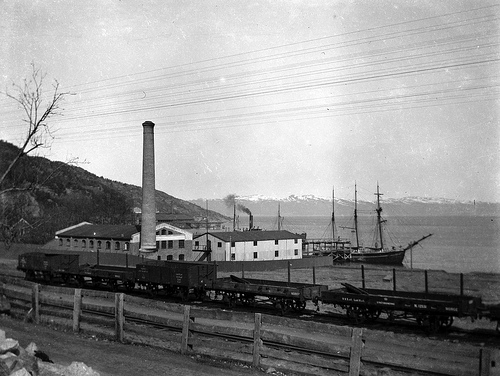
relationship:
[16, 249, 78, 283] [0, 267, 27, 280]
car on rail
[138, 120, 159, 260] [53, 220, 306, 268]
smokestack on factory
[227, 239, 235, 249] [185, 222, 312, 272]
windows on factory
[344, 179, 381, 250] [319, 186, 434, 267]
mast on boat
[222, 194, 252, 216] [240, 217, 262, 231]
smoke coming out of smokestack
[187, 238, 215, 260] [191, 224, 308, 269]
steps on building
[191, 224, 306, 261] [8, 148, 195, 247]
building on hillside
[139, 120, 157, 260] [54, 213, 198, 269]
smokestack on building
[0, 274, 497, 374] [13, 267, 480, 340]
wooden fence near tracks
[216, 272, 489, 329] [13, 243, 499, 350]
cars on train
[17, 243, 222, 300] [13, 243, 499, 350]
caboose on train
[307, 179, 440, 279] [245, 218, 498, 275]
boat on ocean water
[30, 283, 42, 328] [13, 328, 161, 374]
post on dirt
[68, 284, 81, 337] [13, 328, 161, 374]
post on dirt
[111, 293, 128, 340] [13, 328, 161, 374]
post on dirt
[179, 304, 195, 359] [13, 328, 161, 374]
post on dirt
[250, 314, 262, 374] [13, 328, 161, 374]
post on dirt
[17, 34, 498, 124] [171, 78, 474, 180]
power lines across gray sky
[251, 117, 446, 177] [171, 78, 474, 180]
clouds in gray sky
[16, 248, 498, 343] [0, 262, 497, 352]
train on tracks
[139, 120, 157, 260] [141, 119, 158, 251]
smokestack on building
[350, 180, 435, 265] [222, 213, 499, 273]
boat on water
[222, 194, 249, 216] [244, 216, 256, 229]
smoke from smoke stack